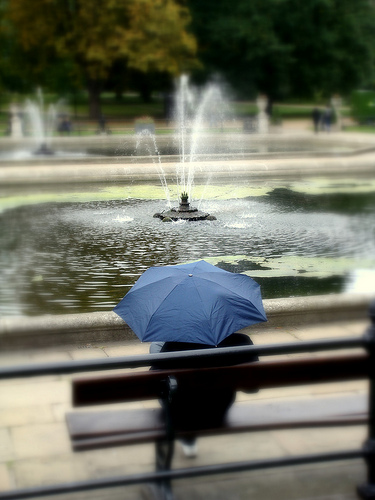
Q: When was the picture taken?
A: Daytime.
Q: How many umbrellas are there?
A: One.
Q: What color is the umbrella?
A: Blue.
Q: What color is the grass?
A: Green.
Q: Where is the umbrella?
A: Over the person.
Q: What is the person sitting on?
A: The bench.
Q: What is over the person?
A: The umbrella.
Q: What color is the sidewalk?
A: Gray.